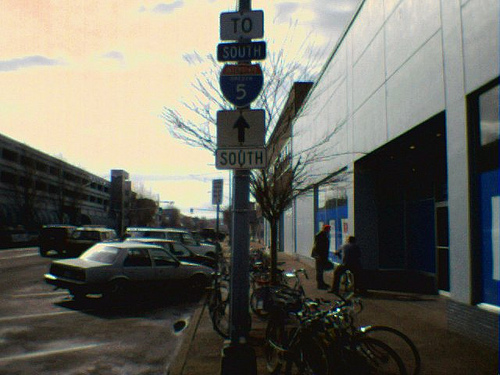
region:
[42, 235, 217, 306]
car parked on the street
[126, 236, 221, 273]
car parked on the street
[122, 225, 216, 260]
car parked on the street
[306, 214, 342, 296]
person on the sidewalk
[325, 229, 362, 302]
person on the sidewalk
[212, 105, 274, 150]
sign on a pole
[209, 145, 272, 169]
sign on a pole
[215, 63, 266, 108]
sign on a pole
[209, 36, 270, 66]
sign on a pole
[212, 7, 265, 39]
sign on a pole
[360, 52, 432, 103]
white building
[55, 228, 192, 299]
car in lot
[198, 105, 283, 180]
street sign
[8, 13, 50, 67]
white clouds in blue sky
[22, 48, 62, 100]
white clouds in blue sky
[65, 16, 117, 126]
white clouds in blue sky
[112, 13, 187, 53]
white clouds in blue sky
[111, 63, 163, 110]
white clouds in blue sky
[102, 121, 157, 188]
white clouds in blue sky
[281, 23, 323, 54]
white clouds in blue sky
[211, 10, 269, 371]
signs on the pole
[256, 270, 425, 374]
several bikes near the pole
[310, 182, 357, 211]
window on the building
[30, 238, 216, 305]
car parked on road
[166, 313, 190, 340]
puddle on the ground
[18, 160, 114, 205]
building with lots of windows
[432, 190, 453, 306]
door of the store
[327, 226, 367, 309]
person sitting on a bike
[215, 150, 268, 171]
sign that says south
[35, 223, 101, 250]
vehicles on the road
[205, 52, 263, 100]
street sign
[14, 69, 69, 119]
white clouds in blue sky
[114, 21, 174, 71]
white clouds in blue sky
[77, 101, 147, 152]
white clouds in blue sky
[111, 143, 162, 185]
white clouds in blue sky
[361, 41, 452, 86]
white building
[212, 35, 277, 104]
The sign is blue.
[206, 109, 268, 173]
The sign is white.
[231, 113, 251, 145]
The arrow is black.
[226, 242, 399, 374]
The bikes are leaning.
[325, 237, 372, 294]
he is on a bike.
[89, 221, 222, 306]
The cars are parked.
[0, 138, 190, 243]
The building is short.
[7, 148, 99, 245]
The trees are bare.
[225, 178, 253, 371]
The pole is metal.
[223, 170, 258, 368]
The pole is silver.